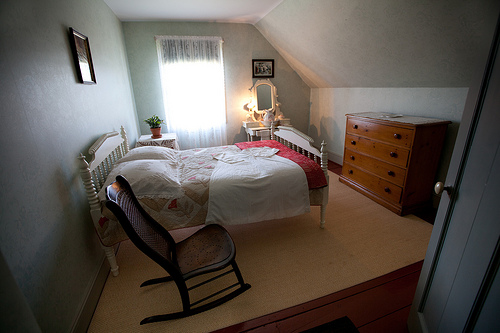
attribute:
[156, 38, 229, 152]
curtains — sheer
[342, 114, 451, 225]
dresser — wooden, brown, wood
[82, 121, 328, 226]
bed — centered, white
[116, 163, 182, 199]
pillow — large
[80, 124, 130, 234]
headboard — white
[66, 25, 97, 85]
picture — reflective, framed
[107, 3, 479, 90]
ceiling — slanted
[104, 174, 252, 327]
rocker — armless, wooden, wood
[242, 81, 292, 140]
vanity — white, small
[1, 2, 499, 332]
bedroom — photographed, small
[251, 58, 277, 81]
picture — framed, small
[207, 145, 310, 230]
nightgown — white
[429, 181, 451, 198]
doorknob — white